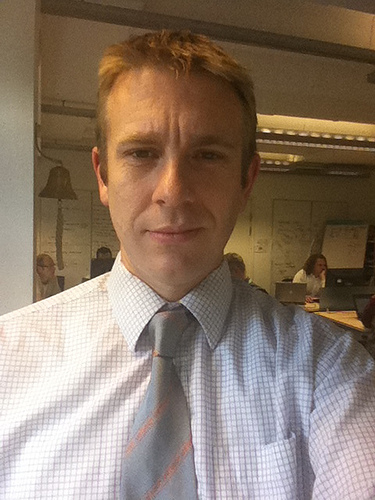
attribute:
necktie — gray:
[140, 297, 237, 492]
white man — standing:
[0, 28, 374, 498]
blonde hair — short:
[83, 17, 257, 187]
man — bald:
[34, 251, 62, 304]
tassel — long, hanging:
[54, 197, 71, 267]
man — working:
[292, 244, 335, 305]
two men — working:
[44, 255, 119, 279]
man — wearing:
[38, 40, 291, 307]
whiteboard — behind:
[265, 194, 364, 298]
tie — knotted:
[112, 282, 228, 447]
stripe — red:
[138, 438, 196, 497]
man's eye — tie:
[116, 140, 227, 167]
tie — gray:
[121, 309, 197, 498]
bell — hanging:
[37, 165, 75, 200]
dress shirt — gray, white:
[0, 249, 373, 498]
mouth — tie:
[143, 218, 207, 237]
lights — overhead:
[261, 127, 370, 174]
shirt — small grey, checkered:
[2, 251, 373, 457]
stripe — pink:
[142, 436, 191, 490]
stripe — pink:
[119, 380, 179, 457]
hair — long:
[300, 252, 327, 277]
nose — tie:
[150, 149, 200, 213]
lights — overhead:
[252, 120, 374, 158]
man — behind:
[0, 28, 371, 497]